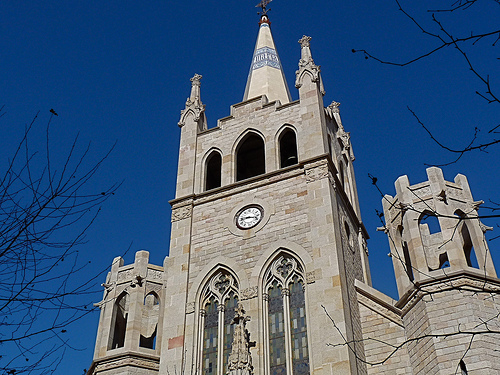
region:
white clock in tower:
[221, 197, 263, 237]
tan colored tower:
[158, 8, 343, 359]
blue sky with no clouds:
[32, 34, 70, 76]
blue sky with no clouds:
[99, 105, 146, 162]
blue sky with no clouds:
[97, 165, 124, 202]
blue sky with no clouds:
[415, 30, 455, 76]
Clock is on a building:
[234, 203, 268, 226]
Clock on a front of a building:
[226, 200, 269, 230]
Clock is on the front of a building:
[225, 200, 273, 234]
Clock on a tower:
[230, 200, 266, 230]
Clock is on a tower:
[230, 200, 266, 231]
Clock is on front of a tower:
[233, 201, 269, 227]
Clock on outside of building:
[230, 205, 269, 232]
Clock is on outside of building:
[234, 204, 267, 231]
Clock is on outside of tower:
[230, 202, 268, 232]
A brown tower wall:
[419, 300, 491, 374]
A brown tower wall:
[367, 312, 412, 372]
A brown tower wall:
[304, 263, 340, 354]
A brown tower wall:
[174, 201, 221, 274]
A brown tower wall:
[265, 187, 328, 254]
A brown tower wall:
[229, 110, 302, 132]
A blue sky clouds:
[87, 113, 164, 238]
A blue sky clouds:
[2, 12, 74, 128]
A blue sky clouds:
[343, 25, 435, 163]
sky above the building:
[70, 17, 160, 92]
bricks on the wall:
[260, 185, 325, 245]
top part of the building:
[220, 0, 285, 47]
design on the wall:
[191, 292, 272, 367]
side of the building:
[302, 171, 353, 301]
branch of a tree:
[345, 31, 430, 91]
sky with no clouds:
[110, 110, 168, 148]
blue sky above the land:
[14, 11, 157, 103]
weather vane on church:
[253, 2, 275, 18]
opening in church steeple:
[229, 129, 269, 179]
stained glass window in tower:
[265, 257, 311, 374]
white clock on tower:
[238, 207, 263, 229]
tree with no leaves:
[2, 106, 134, 374]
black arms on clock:
[238, 214, 259, 222]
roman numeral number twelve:
[247, 207, 254, 213]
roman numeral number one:
[253, 209, 255, 212]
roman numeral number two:
[253, 209, 260, 212]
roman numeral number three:
[256, 212, 261, 217]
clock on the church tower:
[235, 205, 262, 234]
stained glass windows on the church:
[194, 235, 314, 373]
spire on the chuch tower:
[238, 11, 295, 103]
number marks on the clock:
[238, 209, 263, 229]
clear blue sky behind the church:
[0, 2, 498, 362]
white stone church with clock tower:
[109, 11, 489, 373]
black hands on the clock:
[239, 214, 256, 224]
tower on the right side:
[375, 160, 499, 365]